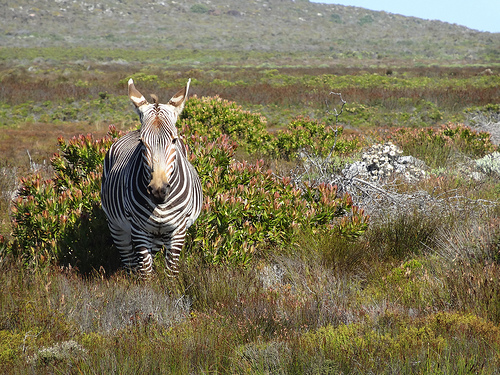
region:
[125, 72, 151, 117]
The left ear of the zebra.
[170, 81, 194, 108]
The right ear of the zebra.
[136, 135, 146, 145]
The left eye of the zebra.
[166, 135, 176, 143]
The right eye of the zebra.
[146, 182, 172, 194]
The nose of the zebra.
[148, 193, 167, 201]
The mouth of the zebra.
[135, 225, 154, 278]
The front left leg of the zebra.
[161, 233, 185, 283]
The front right leg of the zebra.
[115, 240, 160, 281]
The back legs of the zebra.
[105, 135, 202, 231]
The stomach area of the zebra.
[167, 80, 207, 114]
Zebra has black and white ear.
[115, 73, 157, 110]
Zebra has black and white ear.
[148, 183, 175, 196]
Zebra has black nose.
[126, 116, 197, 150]
Zebra has dark eyes.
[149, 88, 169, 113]
Dark hair on top of zebra's mane.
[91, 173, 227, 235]
Zebra is black and white.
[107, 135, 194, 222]
Zebra is covered in stripes.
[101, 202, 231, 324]
Zebra is standing in tall grass.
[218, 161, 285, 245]
Plush greenery behind zebra.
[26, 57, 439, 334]
Zebra is standing in grassy field.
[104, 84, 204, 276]
A big fat zebra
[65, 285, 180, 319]
A grey vegitation in the field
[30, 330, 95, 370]
A grey vegitation in the field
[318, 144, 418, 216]
A grey vegitation in the field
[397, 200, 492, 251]
A grey vegitation in the field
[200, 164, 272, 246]
A green leaf tree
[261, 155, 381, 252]
A green leaf tree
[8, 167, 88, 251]
A green leaf tree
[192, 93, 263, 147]
A green leaf tree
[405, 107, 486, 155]
A green leaf tree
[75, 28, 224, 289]
large zebra looking forward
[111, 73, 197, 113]
perky ears of zebra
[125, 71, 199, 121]
white and black ears of zebra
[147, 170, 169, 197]
black and brown snout of zebra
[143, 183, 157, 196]
large black nostril of zebra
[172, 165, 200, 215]
black and white stripes of zebra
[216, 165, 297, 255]
green bushes with flowers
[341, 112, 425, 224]
white flowers growing in field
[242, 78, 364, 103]
brown bushes growing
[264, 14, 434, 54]
small hill with rocks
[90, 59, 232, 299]
white and black zebra in field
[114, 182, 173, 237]
white and brown stripes on zebra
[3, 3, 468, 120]
small hill behind zebra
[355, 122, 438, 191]
white rocks on field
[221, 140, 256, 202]
pink flowers on bush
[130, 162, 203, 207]
black nose on zebra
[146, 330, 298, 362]
tall grass in field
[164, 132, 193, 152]
small eye of zebra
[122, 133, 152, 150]
small eye of zebra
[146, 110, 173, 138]
small red hair on zebra's head